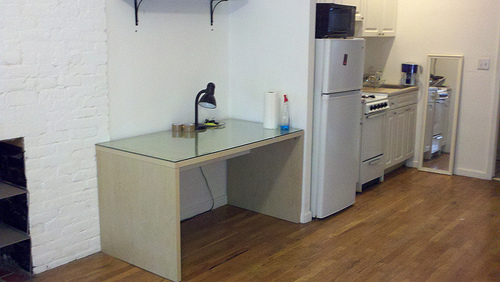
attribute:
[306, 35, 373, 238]
refrigerator — white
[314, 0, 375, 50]
microwave — black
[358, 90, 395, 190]
oven — white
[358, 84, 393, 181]
stove — white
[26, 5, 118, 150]
wall — white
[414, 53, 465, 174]
mirror — rectangular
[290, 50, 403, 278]
refrigerator — white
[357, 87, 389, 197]
gas stove — white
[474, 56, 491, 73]
electrical receptacle — double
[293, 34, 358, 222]
refrigerator — white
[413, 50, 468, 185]
glass — rectangular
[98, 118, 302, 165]
top — rectangular, clear, glass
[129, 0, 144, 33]
shelf bracket — black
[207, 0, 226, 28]
shelf bracket — black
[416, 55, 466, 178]
mirror — full body